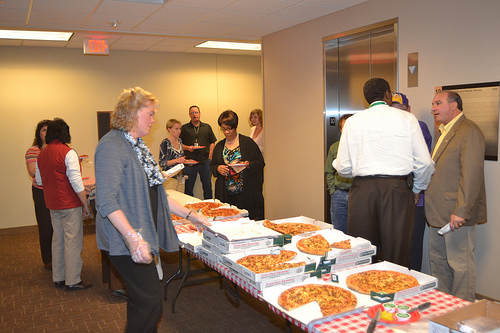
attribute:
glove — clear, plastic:
[124, 227, 155, 265]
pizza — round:
[279, 282, 357, 315]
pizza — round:
[348, 268, 418, 297]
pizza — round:
[264, 217, 321, 237]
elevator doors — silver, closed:
[337, 29, 397, 132]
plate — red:
[367, 301, 421, 326]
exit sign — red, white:
[82, 37, 110, 57]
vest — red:
[35, 140, 82, 209]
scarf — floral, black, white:
[120, 126, 168, 188]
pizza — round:
[202, 206, 239, 219]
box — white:
[220, 245, 316, 283]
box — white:
[331, 259, 439, 305]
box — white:
[285, 226, 370, 262]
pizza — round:
[185, 201, 221, 213]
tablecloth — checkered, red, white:
[183, 248, 472, 331]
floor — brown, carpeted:
[1, 223, 302, 331]